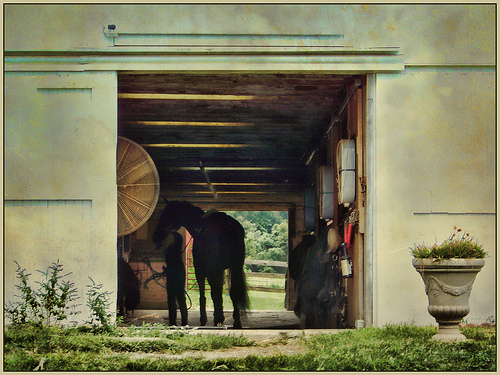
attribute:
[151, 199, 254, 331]
horse — taller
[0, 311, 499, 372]
grass — green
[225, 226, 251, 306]
hair — long